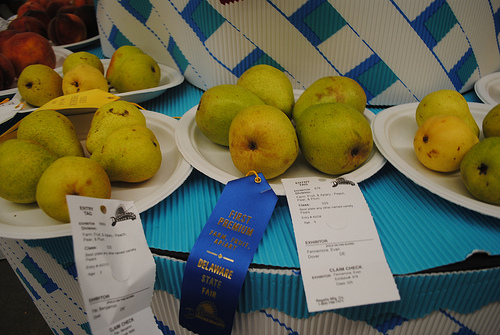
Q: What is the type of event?
A: Contest.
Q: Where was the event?
A: Delaware.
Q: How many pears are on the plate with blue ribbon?
A: Five.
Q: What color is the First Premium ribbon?
A: Blue.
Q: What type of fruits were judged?
A: Pears.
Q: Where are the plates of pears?
A: On display.